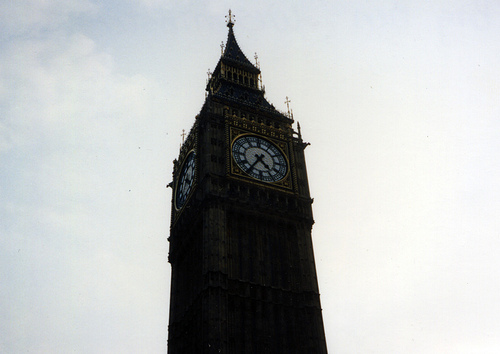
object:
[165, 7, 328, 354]
clock tower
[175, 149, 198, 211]
clock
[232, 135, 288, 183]
clock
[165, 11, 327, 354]
tower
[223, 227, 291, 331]
dark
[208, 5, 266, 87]
spire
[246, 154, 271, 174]
hand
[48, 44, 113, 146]
clouds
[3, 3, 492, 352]
sky